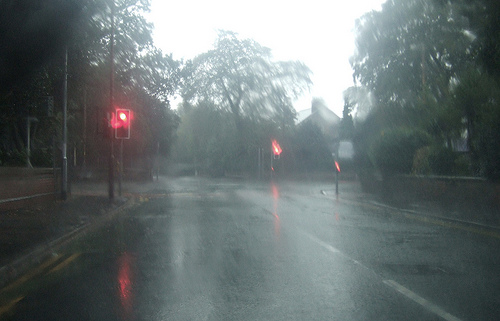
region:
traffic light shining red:
[111, 105, 141, 142]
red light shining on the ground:
[113, 253, 134, 303]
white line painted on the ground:
[285, 229, 464, 319]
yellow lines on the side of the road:
[3, 235, 88, 309]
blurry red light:
[270, 138, 287, 161]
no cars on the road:
[1, 151, 498, 318]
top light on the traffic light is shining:
[109, 106, 136, 142]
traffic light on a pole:
[109, 105, 134, 140]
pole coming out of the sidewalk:
[56, 38, 79, 206]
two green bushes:
[357, 121, 449, 183]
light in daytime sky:
[123, 0, 383, 111]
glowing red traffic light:
[115, 106, 129, 128]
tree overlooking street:
[174, 27, 313, 160]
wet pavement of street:
[28, 178, 493, 320]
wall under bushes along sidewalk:
[381, 175, 498, 209]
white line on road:
[381, 275, 459, 320]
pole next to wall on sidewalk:
[6, 55, 71, 202]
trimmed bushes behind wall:
[371, 127, 494, 214]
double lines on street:
[3, 252, 75, 315]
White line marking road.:
[331, 241, 393, 295]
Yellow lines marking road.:
[12, 258, 80, 280]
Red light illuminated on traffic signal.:
[121, 105, 138, 130]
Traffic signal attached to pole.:
[100, 108, 155, 164]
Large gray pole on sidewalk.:
[46, 105, 79, 200]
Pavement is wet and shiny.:
[145, 218, 225, 294]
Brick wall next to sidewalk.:
[8, 173, 49, 191]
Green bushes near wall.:
[373, 133, 421, 173]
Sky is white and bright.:
[284, 12, 334, 53]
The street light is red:
[100, 93, 147, 148]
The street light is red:
[260, 127, 290, 164]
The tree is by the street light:
[179, 25, 298, 190]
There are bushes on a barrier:
[354, 157, 493, 218]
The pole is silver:
[50, 30, 80, 211]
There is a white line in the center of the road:
[218, 166, 468, 316]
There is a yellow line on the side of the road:
[2, 232, 98, 317]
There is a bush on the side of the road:
[363, 113, 464, 184]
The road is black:
[18, 150, 489, 318]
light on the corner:
[101, 101, 138, 141]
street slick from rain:
[153, 183, 320, 315]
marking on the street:
[386, 272, 444, 318]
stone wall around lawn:
[378, 166, 486, 208]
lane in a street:
[351, 213, 413, 253]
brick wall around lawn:
[5, 160, 71, 200]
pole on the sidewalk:
[48, 48, 82, 200]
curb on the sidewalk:
[98, 210, 110, 221]